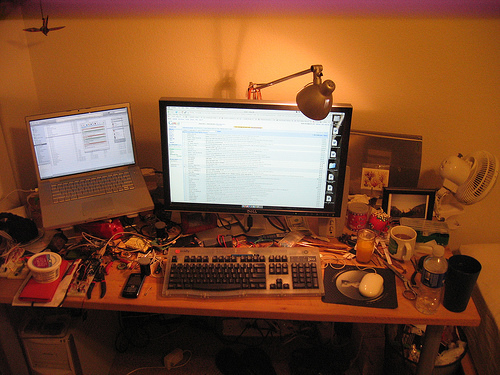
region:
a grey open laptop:
[21, 101, 155, 231]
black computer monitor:
[156, 92, 354, 223]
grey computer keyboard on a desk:
[157, 244, 327, 302]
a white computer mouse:
[358, 269, 383, 299]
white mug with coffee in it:
[386, 224, 416, 264]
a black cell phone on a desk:
[118, 270, 145, 302]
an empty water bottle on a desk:
[413, 242, 445, 318]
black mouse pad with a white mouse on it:
[319, 259, 401, 314]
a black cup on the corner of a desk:
[441, 254, 483, 316]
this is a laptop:
[23, 100, 154, 229]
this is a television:
[156, 93, 352, 220]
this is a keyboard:
[163, 244, 323, 299]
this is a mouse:
[356, 270, 385, 296]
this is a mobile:
[122, 271, 144, 299]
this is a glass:
[353, 224, 378, 265]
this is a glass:
[445, 241, 482, 326]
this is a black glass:
[442, 251, 479, 321]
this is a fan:
[438, 127, 498, 226]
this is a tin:
[26, 248, 62, 281]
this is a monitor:
[162, 116, 342, 206]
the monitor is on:
[181, 112, 301, 197]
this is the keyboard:
[164, 247, 314, 297]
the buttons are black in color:
[175, 251, 263, 286]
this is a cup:
[443, 255, 478, 305]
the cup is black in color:
[441, 253, 480, 305]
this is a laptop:
[29, 100, 136, 220]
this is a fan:
[443, 145, 496, 202]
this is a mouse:
[353, 268, 390, 298]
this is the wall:
[388, 20, 480, 107]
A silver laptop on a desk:
[26, 100, 149, 227]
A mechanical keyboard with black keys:
[161, 243, 326, 299]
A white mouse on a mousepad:
[357, 269, 384, 297]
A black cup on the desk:
[444, 253, 483, 313]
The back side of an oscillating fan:
[438, 155, 468, 189]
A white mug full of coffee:
[387, 224, 417, 260]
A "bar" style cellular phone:
[121, 273, 146, 298]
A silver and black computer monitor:
[157, 95, 344, 220]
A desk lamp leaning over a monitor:
[246, 64, 336, 122]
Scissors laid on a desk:
[383, 258, 420, 300]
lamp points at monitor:
[241, 63, 337, 121]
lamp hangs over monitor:
[244, 61, 339, 121]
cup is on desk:
[444, 246, 481, 312]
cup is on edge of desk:
[442, 253, 479, 315]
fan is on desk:
[432, 145, 493, 220]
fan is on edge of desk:
[434, 149, 499, 217]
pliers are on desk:
[85, 261, 107, 300]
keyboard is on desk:
[157, 242, 327, 302]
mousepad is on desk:
[315, 259, 400, 312]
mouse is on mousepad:
[357, 267, 384, 301]